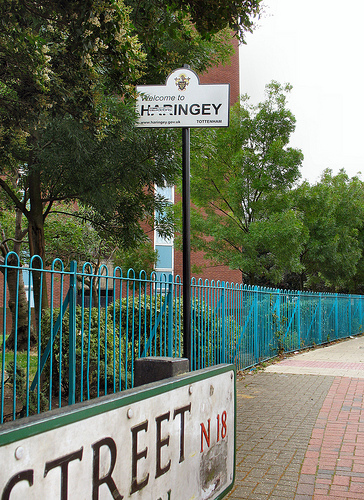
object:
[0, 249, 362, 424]
fence panel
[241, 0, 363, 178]
sky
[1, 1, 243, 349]
wall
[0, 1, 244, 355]
building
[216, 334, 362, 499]
sidewalk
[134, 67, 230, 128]
sign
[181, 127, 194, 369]
pole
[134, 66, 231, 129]
trim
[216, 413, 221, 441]
numbers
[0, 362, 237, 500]
sign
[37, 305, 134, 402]
bushes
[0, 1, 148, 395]
tree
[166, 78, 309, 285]
tree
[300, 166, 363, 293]
tree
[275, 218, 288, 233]
leaves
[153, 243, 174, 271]
window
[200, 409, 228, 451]
lettering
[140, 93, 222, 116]
lettering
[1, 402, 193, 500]
lettering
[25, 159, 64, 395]
trunk